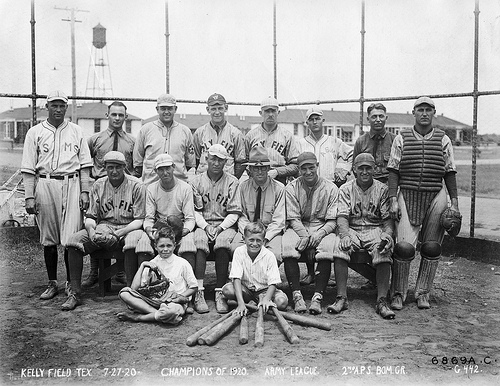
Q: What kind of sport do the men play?
A: Baseball.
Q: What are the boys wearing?
A: Baseball uniforms.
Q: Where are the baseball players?
A: Baseball field.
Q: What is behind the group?
A: A fence.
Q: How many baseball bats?
A: 7.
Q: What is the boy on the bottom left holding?
A: A glove.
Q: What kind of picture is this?
A: Baseball team picture.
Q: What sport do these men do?
A: Baseball.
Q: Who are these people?
A: Baseball players.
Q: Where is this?
A: A baseball field.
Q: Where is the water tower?
A: Next to the electric tower.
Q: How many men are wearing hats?
A: 12.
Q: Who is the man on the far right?
A: The catcher.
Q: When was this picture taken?
A: July 27th, 1920.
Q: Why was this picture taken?
A: Because this team was the army league champions of 1920.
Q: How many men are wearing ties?
A: 3.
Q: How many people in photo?
A: 16.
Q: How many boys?
A: Two.